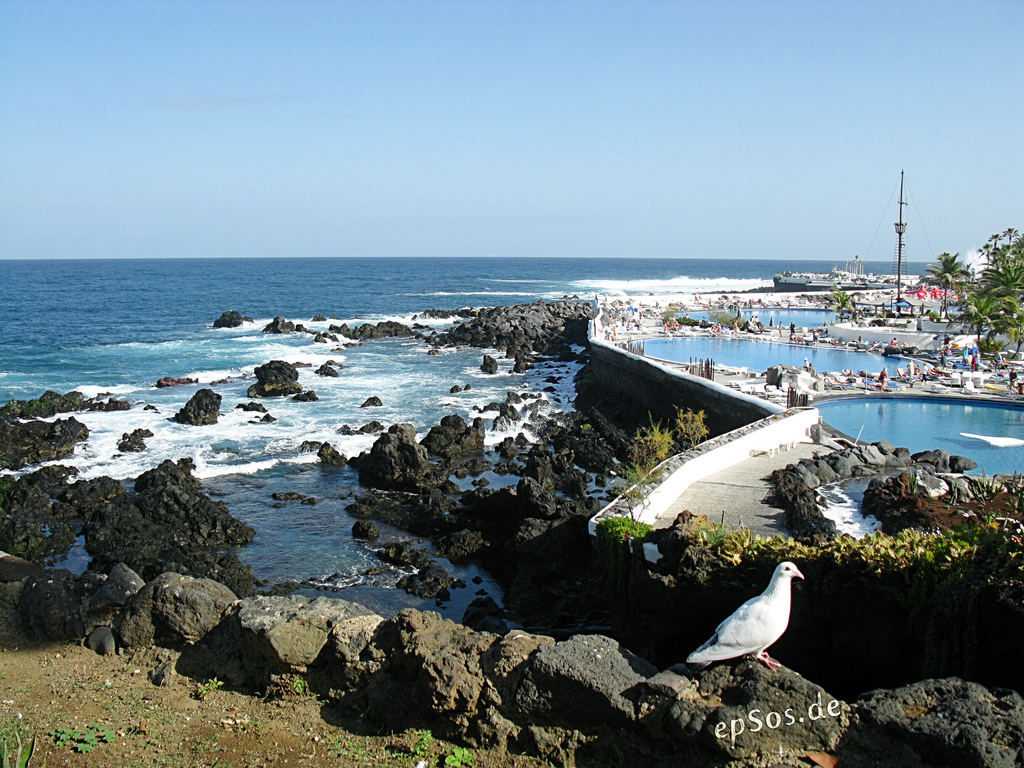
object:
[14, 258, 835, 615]
water body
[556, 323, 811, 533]
retaining wall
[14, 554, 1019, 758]
retaining wall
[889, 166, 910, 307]
crow's nest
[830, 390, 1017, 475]
pool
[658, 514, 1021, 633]
bush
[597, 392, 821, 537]
flower planter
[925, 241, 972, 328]
palm tree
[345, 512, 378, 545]
rock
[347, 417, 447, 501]
rock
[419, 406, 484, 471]
rock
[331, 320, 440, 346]
rock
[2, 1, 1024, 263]
sky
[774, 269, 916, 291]
boat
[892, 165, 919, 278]
mast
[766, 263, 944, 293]
ship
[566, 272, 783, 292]
wave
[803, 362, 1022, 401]
people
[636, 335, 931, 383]
pool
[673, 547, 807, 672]
bird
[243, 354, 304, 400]
rock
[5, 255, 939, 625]
ocean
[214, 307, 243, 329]
rock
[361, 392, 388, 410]
rock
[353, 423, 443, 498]
rock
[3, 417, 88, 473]
rock